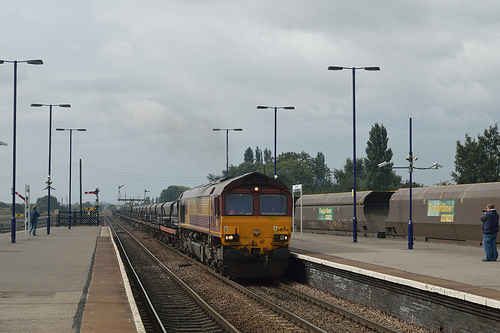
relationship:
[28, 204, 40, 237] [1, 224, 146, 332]
person standing on platform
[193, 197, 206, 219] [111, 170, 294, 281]
label on train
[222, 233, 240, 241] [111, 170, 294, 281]
lights are on train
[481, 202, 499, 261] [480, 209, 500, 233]
man wearing a jacket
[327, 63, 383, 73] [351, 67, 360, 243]
lights are on pole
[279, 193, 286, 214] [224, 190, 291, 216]
windshield wiper on windshield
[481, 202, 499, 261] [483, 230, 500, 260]
man wearing jeans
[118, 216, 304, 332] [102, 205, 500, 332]
rocks are around train tracks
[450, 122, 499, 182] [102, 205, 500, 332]
tree on side of train tracks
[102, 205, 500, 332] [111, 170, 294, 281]
train tracks are for train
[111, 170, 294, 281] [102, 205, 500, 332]
train on train tracks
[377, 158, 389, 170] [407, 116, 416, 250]
security camera on a pole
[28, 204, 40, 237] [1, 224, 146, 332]
person walking on platform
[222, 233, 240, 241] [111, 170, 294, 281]
lights are on front of train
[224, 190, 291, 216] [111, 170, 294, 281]
windshield on front of train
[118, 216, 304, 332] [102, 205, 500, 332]
rocks are between train tracks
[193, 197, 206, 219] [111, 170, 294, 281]
label on side of train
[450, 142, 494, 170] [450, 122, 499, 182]
leaves are on tree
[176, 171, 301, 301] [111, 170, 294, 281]
cart in front of train